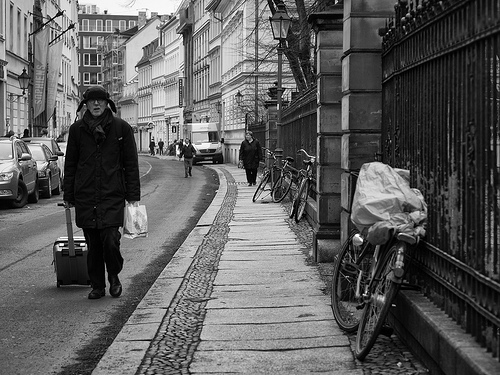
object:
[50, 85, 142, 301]
man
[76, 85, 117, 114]
hat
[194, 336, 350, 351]
tiles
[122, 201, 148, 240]
bag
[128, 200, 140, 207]
hand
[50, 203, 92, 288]
luggage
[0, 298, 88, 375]
road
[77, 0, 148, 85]
building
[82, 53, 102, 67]
windows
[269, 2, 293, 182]
light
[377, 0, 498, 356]
fence bars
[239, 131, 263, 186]
woman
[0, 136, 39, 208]
car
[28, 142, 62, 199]
car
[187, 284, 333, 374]
sidewalk